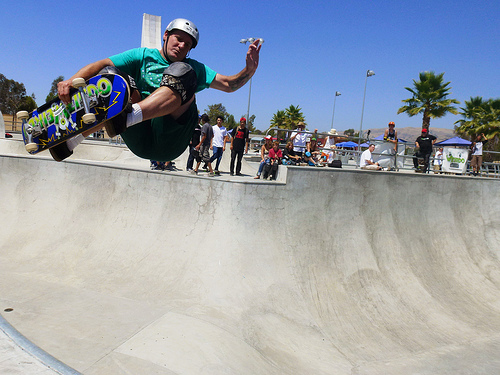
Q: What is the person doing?
A: Skateboarding.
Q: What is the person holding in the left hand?
A: Skateboard.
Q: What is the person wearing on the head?
A: Helmet.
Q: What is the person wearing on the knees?
A: Knee pads.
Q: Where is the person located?
A: Skatepark.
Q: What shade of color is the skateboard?
A: Blue, yellow and green.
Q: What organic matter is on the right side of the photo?
A: Palm trees.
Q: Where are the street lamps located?
A: Right side of the photo.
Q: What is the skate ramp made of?
A: Cement.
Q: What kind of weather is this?
A: Sunny and clear.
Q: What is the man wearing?
A: Green shirt.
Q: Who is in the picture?
A: A skateboarder.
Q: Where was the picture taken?
A: In the skateboarding park.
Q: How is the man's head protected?
A: With the helmet.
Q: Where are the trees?
A: Behind the people.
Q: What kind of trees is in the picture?
A: Palm trees.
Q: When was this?
A: Daytime.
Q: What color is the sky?
A: Blue.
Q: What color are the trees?
A: Green.